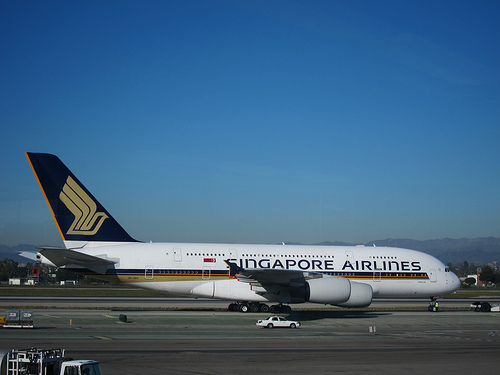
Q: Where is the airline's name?
A: On plane.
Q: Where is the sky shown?
A: Over mountains.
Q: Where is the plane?
A: On tarmac.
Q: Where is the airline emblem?
A: Tail.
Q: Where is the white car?
A: Near plane.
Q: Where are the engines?
A: On wings.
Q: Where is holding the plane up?
A: Landing gear.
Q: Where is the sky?
A: Behind plane.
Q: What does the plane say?
A: Singapore Airlines.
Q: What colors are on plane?
A: White blue gold.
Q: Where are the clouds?
A: No clouds.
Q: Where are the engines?
A: On plane.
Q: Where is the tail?
A: On plane.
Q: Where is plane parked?
A: Tarmac.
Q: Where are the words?
A: On plane.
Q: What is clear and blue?
A: The sky.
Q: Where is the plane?
A: On the tarmac.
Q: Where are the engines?
A: Under the wing.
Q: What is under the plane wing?
A: Car.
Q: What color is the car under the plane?
A: White.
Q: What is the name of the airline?
A: Singapore Airlines.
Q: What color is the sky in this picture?
A: Blue.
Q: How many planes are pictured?
A: One.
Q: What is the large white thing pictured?
A: Jet/airplane.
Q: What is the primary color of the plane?
A: White.